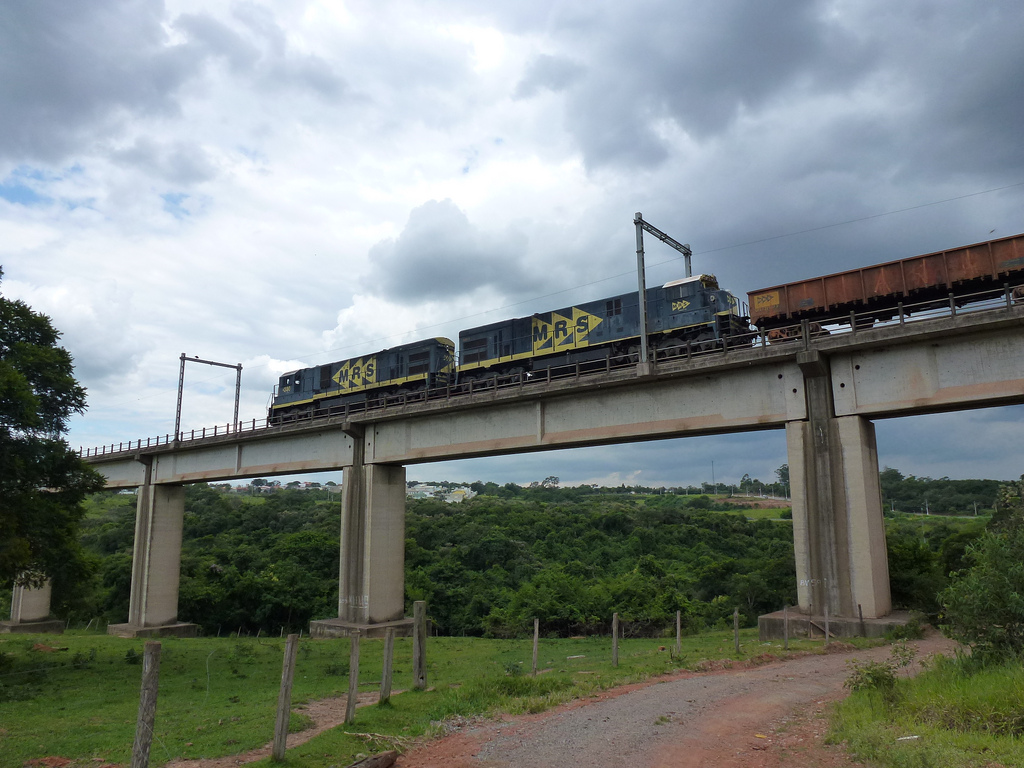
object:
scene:
[0, 0, 1024, 768]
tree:
[447, 564, 534, 633]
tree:
[479, 559, 613, 641]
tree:
[558, 554, 675, 639]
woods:
[17, 464, 1024, 667]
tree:
[882, 516, 950, 611]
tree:
[925, 525, 961, 552]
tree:
[180, 557, 257, 626]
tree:
[176, 526, 282, 621]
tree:
[254, 562, 341, 623]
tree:
[44, 503, 132, 629]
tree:
[79, 503, 137, 550]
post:
[135, 640, 162, 766]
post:
[273, 634, 300, 763]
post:
[343, 631, 359, 726]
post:
[380, 627, 396, 705]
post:
[413, 600, 427, 690]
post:
[532, 618, 538, 677]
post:
[611, 613, 617, 667]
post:
[677, 611, 682, 654]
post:
[733, 607, 739, 654]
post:
[824, 603, 829, 641]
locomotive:
[265, 337, 456, 426]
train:
[265, 233, 1024, 427]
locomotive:
[455, 273, 757, 390]